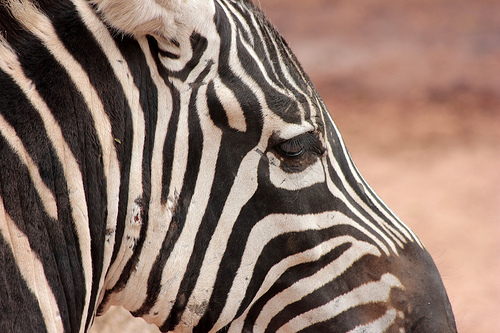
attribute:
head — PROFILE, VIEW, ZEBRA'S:
[172, 15, 476, 329]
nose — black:
[396, 242, 459, 331]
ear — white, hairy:
[95, 2, 218, 37]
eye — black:
[274, 133, 310, 157]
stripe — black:
[212, 1, 265, 133]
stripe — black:
[233, 23, 303, 124]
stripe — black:
[220, 1, 253, 47]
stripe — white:
[216, 1, 270, 114]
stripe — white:
[238, 29, 291, 96]